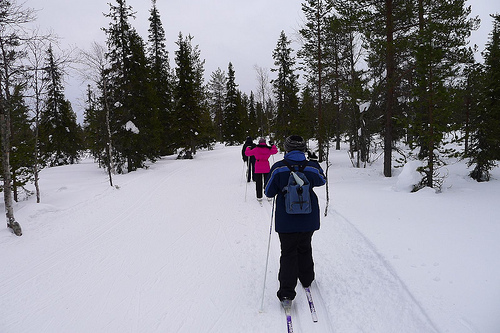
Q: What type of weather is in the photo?
A: It is overcast.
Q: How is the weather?
A: It is overcast.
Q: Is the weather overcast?
A: Yes, it is overcast.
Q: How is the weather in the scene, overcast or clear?
A: It is overcast.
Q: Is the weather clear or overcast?
A: It is overcast.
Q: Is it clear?
A: No, it is overcast.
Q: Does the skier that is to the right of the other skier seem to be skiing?
A: Yes, the skier is skiing.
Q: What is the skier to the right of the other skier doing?
A: The skier is skiing.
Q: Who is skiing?
A: The skier is skiing.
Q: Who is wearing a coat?
A: The skier is wearing a coat.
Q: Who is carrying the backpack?
A: The skier is carrying the backpack.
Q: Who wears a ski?
A: The skier wears a ski.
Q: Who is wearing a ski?
A: The skier is wearing a ski.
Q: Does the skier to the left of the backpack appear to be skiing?
A: Yes, the skier is skiing.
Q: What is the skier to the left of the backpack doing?
A: The skier is skiing.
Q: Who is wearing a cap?
A: The skier is wearing a cap.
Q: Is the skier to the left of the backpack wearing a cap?
A: Yes, the skier is wearing a cap.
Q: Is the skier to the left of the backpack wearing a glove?
A: No, the skier is wearing a cap.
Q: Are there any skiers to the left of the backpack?
A: Yes, there is a skier to the left of the backpack.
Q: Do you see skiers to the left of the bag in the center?
A: Yes, there is a skier to the left of the backpack.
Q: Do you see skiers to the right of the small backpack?
A: No, the skier is to the left of the backpack.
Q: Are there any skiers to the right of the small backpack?
A: No, the skier is to the left of the backpack.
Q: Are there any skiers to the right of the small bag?
A: No, the skier is to the left of the backpack.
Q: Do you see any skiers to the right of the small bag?
A: No, the skier is to the left of the backpack.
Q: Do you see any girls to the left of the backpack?
A: No, there is a skier to the left of the backpack.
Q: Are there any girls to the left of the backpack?
A: No, there is a skier to the left of the backpack.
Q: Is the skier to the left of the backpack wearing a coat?
A: Yes, the skier is wearing a coat.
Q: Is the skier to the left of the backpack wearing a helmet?
A: No, the skier is wearing a coat.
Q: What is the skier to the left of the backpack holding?
A: The skier is holding the pole.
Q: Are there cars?
A: No, there are no cars.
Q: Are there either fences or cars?
A: No, there are no cars or fences.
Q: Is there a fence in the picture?
A: No, there are no fences.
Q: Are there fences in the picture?
A: No, there are no fences.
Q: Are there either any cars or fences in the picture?
A: No, there are no fences or cars.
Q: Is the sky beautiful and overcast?
A: Yes, the sky is beautiful and overcast.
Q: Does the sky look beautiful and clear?
A: No, the sky is beautiful but overcast.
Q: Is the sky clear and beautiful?
A: No, the sky is beautiful but overcast.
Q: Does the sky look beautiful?
A: Yes, the sky is beautiful.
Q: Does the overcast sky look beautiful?
A: Yes, the sky is beautiful.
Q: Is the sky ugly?
A: No, the sky is beautiful.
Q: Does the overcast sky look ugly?
A: No, the sky is beautiful.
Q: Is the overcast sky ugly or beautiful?
A: The sky is beautiful.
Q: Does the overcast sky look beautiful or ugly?
A: The sky is beautiful.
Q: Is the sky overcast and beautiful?
A: Yes, the sky is overcast and beautiful.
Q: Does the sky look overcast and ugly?
A: No, the sky is overcast but beautiful.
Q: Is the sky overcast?
A: Yes, the sky is overcast.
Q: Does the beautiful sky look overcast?
A: Yes, the sky is overcast.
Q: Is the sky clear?
A: No, the sky is overcast.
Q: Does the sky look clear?
A: No, the sky is overcast.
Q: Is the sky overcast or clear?
A: The sky is overcast.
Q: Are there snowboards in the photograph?
A: No, there are no snowboards.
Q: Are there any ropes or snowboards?
A: No, there are no snowboards or ropes.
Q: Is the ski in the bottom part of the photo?
A: Yes, the ski is in the bottom of the image.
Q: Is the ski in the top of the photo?
A: No, the ski is in the bottom of the image.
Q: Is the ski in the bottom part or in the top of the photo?
A: The ski is in the bottom of the image.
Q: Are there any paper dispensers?
A: No, there are no paper dispensers.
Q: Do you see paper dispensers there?
A: No, there are no paper dispensers.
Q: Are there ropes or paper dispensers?
A: No, there are no paper dispensers or ropes.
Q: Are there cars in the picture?
A: No, there are no cars.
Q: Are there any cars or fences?
A: No, there are no cars or fences.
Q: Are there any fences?
A: No, there are no fences.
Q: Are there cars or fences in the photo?
A: No, there are no fences or cars.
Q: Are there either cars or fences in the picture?
A: No, there are no fences or cars.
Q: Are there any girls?
A: No, there are no girls.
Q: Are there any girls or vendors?
A: No, there are no girls or vendors.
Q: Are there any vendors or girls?
A: No, there are no girls or vendors.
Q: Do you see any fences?
A: No, there are no fences.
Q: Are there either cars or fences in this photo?
A: No, there are no fences or cars.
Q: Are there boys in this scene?
A: No, there are no boys.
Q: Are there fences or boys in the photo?
A: No, there are no boys or fences.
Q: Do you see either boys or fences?
A: No, there are no boys or fences.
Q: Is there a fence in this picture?
A: No, there are no fences.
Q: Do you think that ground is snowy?
A: Yes, the ground is snowy.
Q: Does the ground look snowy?
A: Yes, the ground is snowy.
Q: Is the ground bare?
A: No, the ground is snowy.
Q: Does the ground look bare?
A: No, the ground is snowy.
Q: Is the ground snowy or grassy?
A: The ground is snowy.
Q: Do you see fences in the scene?
A: No, there are no fences.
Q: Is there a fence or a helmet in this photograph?
A: No, there are no fences or helmets.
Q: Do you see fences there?
A: No, there are no fences.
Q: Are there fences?
A: No, there are no fences.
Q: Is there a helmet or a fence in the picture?
A: No, there are no fences or helmets.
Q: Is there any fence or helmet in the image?
A: No, there are no fences or helmets.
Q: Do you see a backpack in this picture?
A: Yes, there is a backpack.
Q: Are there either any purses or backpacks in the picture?
A: Yes, there is a backpack.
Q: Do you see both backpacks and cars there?
A: No, there is a backpack but no cars.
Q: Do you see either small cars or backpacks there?
A: Yes, there is a small backpack.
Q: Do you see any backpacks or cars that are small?
A: Yes, the backpack is small.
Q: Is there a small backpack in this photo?
A: Yes, there is a small backpack.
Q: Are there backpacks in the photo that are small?
A: Yes, there is a backpack that is small.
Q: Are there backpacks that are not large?
A: Yes, there is a small backpack.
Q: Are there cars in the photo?
A: No, there are no cars.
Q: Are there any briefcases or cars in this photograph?
A: No, there are no cars or briefcases.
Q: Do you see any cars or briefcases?
A: No, there are no cars or briefcases.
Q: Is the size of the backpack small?
A: Yes, the backpack is small.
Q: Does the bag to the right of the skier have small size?
A: Yes, the backpack is small.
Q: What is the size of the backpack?
A: The backpack is small.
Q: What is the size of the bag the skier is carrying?
A: The backpack is small.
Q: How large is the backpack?
A: The backpack is small.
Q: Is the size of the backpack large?
A: No, the backpack is small.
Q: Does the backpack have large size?
A: No, the backpack is small.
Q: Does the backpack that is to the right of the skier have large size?
A: No, the backpack is small.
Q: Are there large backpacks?
A: No, there is a backpack but it is small.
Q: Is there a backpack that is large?
A: No, there is a backpack but it is small.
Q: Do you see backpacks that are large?
A: No, there is a backpack but it is small.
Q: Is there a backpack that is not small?
A: No, there is a backpack but it is small.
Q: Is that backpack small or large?
A: The backpack is small.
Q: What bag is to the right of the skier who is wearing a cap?
A: The bag is a backpack.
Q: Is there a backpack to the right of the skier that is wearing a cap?
A: Yes, there is a backpack to the right of the skier.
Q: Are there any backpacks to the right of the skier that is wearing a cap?
A: Yes, there is a backpack to the right of the skier.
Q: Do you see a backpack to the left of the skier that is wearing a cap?
A: No, the backpack is to the right of the skier.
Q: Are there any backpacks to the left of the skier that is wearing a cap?
A: No, the backpack is to the right of the skier.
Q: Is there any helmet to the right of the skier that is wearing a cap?
A: No, there is a backpack to the right of the skier.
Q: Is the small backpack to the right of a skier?
A: Yes, the backpack is to the right of a skier.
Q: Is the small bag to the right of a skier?
A: Yes, the backpack is to the right of a skier.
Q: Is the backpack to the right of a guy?
A: No, the backpack is to the right of a skier.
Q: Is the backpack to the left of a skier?
A: No, the backpack is to the right of a skier.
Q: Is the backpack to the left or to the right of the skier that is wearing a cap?
A: The backpack is to the right of the skier.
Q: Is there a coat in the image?
A: Yes, there is a coat.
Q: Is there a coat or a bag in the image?
A: Yes, there is a coat.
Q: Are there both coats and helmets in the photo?
A: No, there is a coat but no helmets.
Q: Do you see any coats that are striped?
A: Yes, there is a striped coat.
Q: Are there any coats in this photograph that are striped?
A: Yes, there is a coat that is striped.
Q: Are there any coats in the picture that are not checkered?
A: Yes, there is a striped coat.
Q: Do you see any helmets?
A: No, there are no helmets.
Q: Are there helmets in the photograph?
A: No, there are no helmets.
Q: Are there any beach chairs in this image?
A: No, there are no beach chairs.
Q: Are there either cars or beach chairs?
A: No, there are no beach chairs or cars.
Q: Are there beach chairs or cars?
A: No, there are no beach chairs or cars.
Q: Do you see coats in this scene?
A: Yes, there is a coat.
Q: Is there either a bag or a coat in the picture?
A: Yes, there is a coat.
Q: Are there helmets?
A: No, there are no helmets.